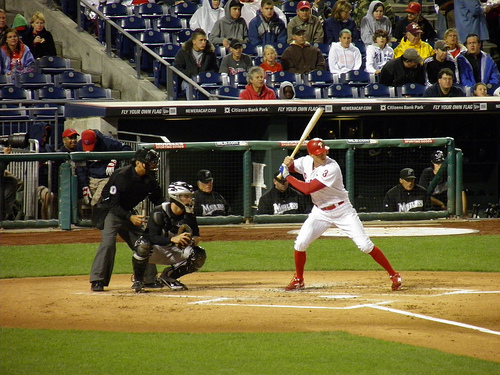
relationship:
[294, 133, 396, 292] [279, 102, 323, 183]
man with bat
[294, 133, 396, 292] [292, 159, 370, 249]
man in uniform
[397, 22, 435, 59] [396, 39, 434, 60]
man in shirt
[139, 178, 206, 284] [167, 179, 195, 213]
man with helmet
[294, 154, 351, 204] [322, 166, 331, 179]
shirt with three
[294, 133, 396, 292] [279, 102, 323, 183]
man holding bat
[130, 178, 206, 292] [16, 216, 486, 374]
man are on top of field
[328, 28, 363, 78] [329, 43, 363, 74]
person wearing white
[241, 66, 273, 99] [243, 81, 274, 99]
woman wearing hoodie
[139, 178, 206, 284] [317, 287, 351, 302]
catcher behind plate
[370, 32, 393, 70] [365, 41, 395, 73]
person wearing sweatshirt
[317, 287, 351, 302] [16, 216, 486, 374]
plate on field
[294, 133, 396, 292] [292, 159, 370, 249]
man wearing uniform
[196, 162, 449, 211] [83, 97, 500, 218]
team in dugout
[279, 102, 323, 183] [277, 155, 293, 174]
bat in hand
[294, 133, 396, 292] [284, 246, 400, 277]
man wearing socks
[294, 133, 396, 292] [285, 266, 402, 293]
man wearing sneakers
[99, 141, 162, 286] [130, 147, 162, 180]
man wearing helmet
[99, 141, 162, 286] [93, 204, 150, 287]
man wearing pants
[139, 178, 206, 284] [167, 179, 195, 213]
man wears helmet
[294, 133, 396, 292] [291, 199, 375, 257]
man wears pants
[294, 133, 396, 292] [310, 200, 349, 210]
man wears belt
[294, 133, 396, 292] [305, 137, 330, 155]
man wearing helmet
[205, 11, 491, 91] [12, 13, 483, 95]
fans in bleechers bleachers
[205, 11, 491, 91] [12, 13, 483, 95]
speactators in stands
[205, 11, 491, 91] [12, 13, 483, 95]
spectators in stands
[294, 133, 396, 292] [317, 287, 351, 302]
player at plate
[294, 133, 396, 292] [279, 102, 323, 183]
player holding bat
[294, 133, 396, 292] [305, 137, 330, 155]
player wearing helmet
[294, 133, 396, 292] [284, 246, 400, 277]
player wearing socks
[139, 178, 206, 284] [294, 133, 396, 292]
catcher behind batter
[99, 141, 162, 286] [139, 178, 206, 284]
umpire behind catcher